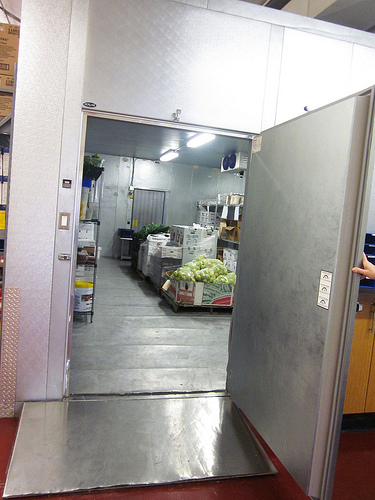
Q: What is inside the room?
A: Boxes, vegetables, and shelves.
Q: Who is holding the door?
A: A person.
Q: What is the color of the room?
A: Silver.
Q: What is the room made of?
A: Metal.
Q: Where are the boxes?
A: Inside the room.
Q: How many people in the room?
A: Zero.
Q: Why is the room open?
A: To show to someone.